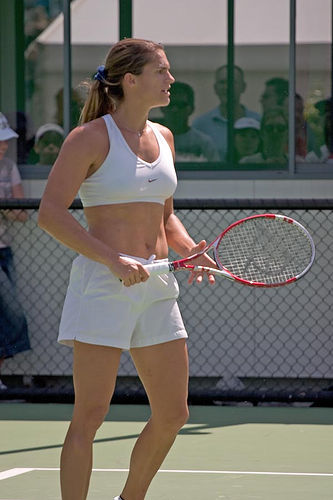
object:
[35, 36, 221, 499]
person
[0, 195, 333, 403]
fence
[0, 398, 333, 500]
court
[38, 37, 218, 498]
girl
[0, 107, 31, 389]
people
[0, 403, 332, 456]
shadow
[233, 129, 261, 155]
ground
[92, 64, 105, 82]
bow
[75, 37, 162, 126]
hair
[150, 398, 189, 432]
knee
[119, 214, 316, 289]
racket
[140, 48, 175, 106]
face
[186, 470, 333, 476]
white line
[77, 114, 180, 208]
sports bra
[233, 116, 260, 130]
white cap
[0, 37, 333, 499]
match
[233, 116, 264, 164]
girl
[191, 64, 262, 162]
people watching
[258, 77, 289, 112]
people watching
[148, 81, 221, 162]
people watching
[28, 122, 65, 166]
people watching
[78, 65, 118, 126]
long hair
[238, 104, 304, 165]
people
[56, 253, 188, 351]
shorts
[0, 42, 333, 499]
event